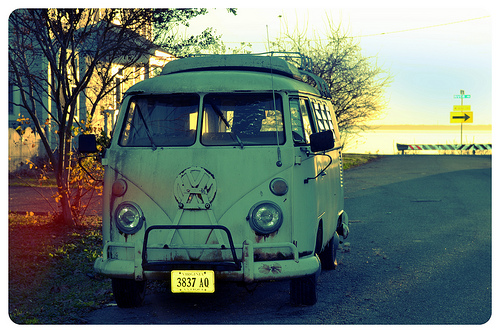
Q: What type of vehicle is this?
A: Volkswagon Bug.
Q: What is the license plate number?
A: 3837 AO.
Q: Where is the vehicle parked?
A: Road.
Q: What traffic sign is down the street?
A: Yellow and black directional.